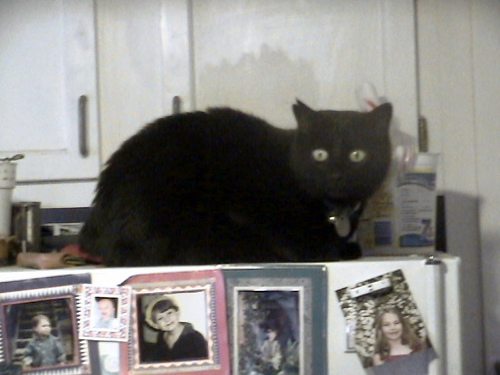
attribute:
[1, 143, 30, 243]
bucket — White 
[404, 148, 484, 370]
refrigerator — White 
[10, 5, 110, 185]
door — cabinet 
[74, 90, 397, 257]
cat — Black, Left ear 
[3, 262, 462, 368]
pictures — family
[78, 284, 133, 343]
pictures — baby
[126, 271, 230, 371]
pictures — child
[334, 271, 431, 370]
pictures — young lady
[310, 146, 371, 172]
eyes — green 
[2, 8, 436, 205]
cabinets — white 